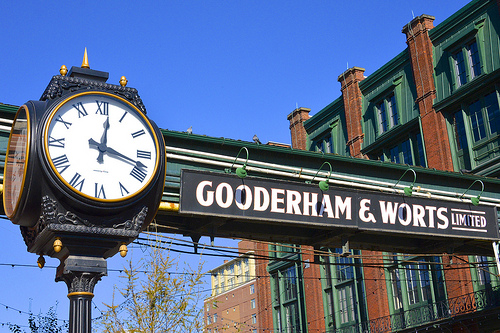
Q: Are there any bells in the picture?
A: No, there are no bells.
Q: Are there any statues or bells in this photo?
A: No, there are no bells or statues.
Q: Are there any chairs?
A: No, there are no chairs.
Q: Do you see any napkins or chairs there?
A: No, there are no chairs or napkins.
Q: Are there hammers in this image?
A: No, there are no hammers.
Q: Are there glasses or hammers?
A: No, there are no hammers or glasses.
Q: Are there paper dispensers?
A: No, there are no paper dispensers.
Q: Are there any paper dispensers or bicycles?
A: No, there are no paper dispensers or bicycles.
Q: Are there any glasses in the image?
A: No, there are no glasses.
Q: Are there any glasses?
A: No, there are no glasses.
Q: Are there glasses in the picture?
A: No, there are no glasses.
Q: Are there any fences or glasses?
A: No, there are no glasses or fences.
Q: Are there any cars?
A: No, there are no cars.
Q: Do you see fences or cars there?
A: No, there are no cars or fences.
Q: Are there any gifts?
A: No, there are no gifts.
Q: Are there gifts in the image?
A: No, there are no gifts.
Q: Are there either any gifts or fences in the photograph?
A: No, there are no gifts or fences.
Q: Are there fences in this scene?
A: No, there are no fences.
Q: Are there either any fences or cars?
A: No, there are no fences or cars.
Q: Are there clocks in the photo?
A: Yes, there is a clock.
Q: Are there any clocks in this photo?
A: Yes, there is a clock.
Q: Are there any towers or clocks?
A: Yes, there is a clock.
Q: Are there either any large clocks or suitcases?
A: Yes, there is a large clock.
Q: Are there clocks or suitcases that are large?
A: Yes, the clock is large.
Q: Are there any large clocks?
A: Yes, there is a large clock.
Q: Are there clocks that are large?
A: Yes, there is a clock that is large.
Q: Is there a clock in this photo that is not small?
A: Yes, there is a large clock.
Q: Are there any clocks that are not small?
A: Yes, there is a large clock.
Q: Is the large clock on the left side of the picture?
A: Yes, the clock is on the left of the image.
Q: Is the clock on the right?
A: No, the clock is on the left of the image.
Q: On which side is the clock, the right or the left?
A: The clock is on the left of the image.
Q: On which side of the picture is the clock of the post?
A: The clock is on the left of the image.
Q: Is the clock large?
A: Yes, the clock is large.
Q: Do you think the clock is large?
A: Yes, the clock is large.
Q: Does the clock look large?
A: Yes, the clock is large.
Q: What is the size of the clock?
A: The clock is large.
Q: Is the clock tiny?
A: No, the clock is large.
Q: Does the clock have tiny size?
A: No, the clock is large.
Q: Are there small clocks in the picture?
A: No, there is a clock but it is large.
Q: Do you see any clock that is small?
A: No, there is a clock but it is large.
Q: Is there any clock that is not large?
A: No, there is a clock but it is large.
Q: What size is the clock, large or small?
A: The clock is large.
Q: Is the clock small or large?
A: The clock is large.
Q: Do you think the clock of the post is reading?
A: Yes, the clock is reading.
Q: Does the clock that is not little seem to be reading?
A: Yes, the clock is reading.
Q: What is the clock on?
A: The clock is on the post.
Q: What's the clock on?
A: The clock is on the post.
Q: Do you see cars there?
A: No, there are no cars.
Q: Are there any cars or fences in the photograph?
A: No, there are no cars or fences.